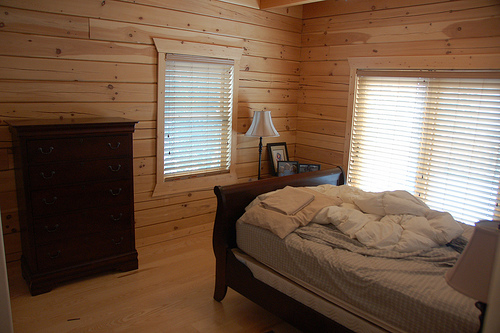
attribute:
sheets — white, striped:
[243, 196, 479, 319]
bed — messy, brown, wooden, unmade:
[206, 168, 492, 327]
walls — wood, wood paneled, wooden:
[16, 6, 344, 259]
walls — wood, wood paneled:
[307, 5, 497, 64]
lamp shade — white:
[244, 109, 279, 138]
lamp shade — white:
[446, 219, 498, 309]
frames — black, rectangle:
[266, 141, 321, 175]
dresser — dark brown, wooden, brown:
[5, 115, 140, 298]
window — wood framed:
[150, 35, 243, 197]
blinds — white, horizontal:
[167, 57, 228, 170]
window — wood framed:
[346, 55, 499, 220]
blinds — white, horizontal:
[358, 76, 494, 207]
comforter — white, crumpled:
[340, 185, 459, 255]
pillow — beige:
[237, 184, 340, 238]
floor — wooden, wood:
[11, 264, 229, 332]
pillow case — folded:
[259, 185, 314, 214]